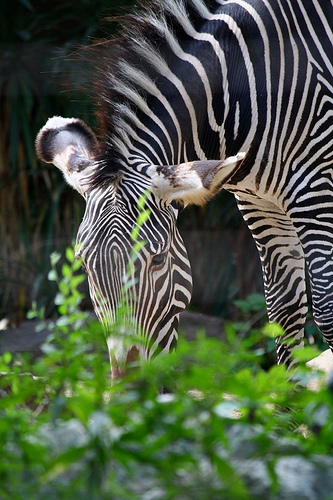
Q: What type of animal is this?
A: Zebra.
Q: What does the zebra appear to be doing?
A: Eating.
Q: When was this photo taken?
A: Daytime.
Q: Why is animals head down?
A: To reach food.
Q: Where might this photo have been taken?
A: Zoo.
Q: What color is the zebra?
A: Black and white.